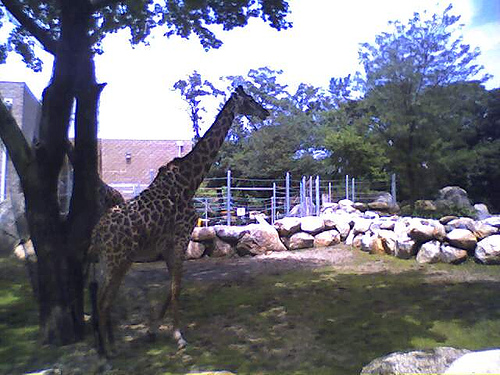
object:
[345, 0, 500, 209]
trees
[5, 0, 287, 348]
tree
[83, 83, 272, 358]
giraffe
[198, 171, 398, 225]
fence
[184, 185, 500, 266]
rocks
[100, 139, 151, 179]
building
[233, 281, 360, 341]
grass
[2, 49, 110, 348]
tree trunk